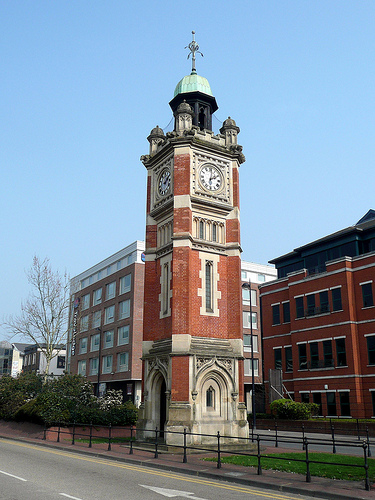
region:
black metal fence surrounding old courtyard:
[40, 415, 367, 490]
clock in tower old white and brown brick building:
[187, 148, 238, 205]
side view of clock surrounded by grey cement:
[149, 154, 173, 210]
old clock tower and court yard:
[135, 25, 373, 492]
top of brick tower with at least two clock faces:
[138, 28, 248, 259]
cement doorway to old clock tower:
[140, 350, 184, 447]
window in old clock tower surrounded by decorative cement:
[192, 347, 241, 447]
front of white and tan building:
[63, 238, 140, 403]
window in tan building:
[100, 302, 117, 325]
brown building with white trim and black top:
[245, 207, 373, 435]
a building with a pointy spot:
[132, 17, 262, 158]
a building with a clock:
[72, 16, 284, 348]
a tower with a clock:
[108, 105, 300, 459]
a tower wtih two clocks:
[123, 113, 282, 403]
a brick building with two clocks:
[136, 46, 289, 370]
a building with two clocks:
[118, 52, 268, 386]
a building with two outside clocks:
[89, 25, 284, 379]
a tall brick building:
[109, 12, 310, 487]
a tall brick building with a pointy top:
[136, 22, 275, 455]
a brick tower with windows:
[113, 49, 281, 469]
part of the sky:
[270, 52, 314, 93]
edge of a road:
[129, 441, 171, 475]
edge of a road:
[136, 451, 176, 482]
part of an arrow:
[135, 471, 166, 496]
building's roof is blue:
[160, 56, 220, 105]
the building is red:
[147, 158, 262, 447]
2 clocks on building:
[141, 154, 252, 214]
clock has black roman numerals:
[198, 158, 226, 194]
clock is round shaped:
[199, 156, 229, 192]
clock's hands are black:
[201, 164, 226, 192]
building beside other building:
[251, 251, 357, 445]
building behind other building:
[52, 235, 143, 401]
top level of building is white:
[52, 239, 139, 286]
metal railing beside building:
[35, 398, 369, 493]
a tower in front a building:
[49, 7, 278, 443]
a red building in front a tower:
[244, 208, 373, 423]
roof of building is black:
[255, 194, 373, 288]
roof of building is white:
[50, 238, 144, 303]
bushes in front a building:
[0, 358, 142, 441]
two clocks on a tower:
[141, 144, 240, 210]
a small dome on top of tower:
[163, 62, 226, 113]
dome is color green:
[166, 62, 226, 115]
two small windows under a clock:
[185, 206, 234, 247]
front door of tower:
[133, 359, 175, 449]